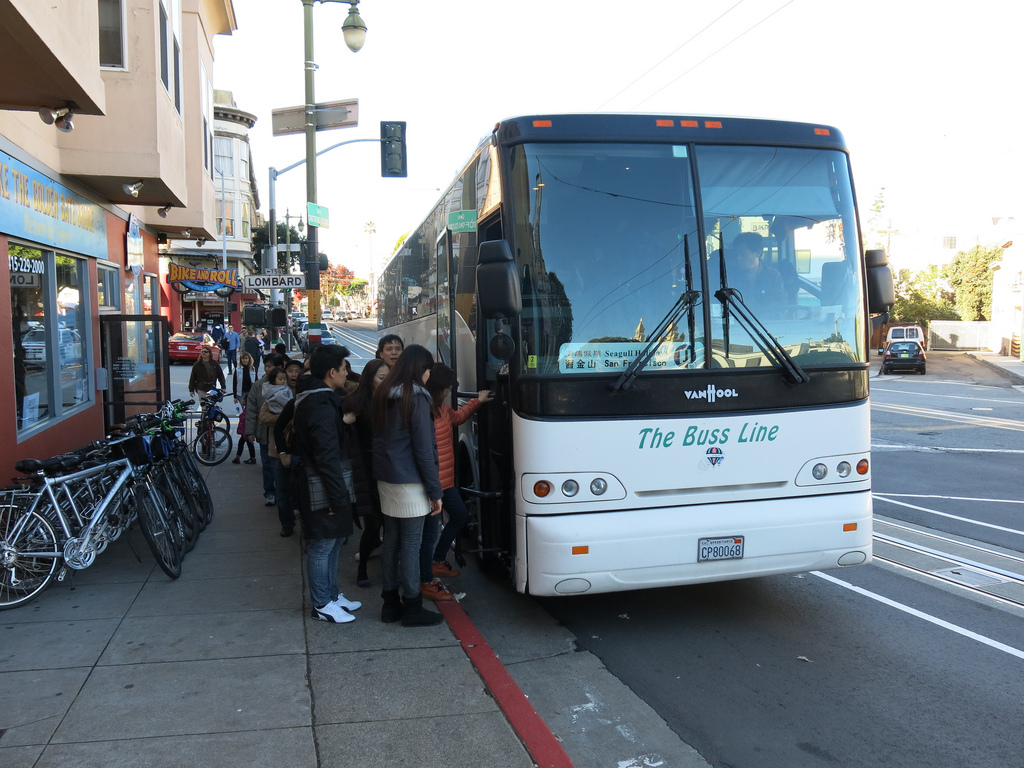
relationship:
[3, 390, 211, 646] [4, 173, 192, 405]
bicycles outside a store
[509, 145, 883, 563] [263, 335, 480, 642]
bus picking up passengers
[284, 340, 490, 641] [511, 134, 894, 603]
passengers waiting to board bus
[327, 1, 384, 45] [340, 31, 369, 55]
lamp with bulb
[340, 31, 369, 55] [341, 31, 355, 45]
bulb over bulb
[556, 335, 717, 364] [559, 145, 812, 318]
sign in window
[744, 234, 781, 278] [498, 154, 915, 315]
driver visible through windshield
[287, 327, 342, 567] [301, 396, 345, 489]
person wearing jacket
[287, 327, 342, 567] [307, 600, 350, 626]
person wearing shoes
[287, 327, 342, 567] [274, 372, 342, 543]
person wearing jacket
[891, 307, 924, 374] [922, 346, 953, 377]
vehicles parked in driveway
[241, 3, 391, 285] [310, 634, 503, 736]
light on the sidewalk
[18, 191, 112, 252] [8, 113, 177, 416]
sign on the building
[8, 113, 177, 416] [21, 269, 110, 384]
building above thr window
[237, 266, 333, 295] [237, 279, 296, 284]
sign with letters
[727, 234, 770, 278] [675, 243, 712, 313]
driver sitting in seat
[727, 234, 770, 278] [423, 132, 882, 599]
driver on the bus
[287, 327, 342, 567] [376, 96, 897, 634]
person lined up bus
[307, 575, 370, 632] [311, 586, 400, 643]
shoes on feet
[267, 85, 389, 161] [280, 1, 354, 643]
sign on pole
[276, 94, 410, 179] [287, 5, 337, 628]
sign on pole